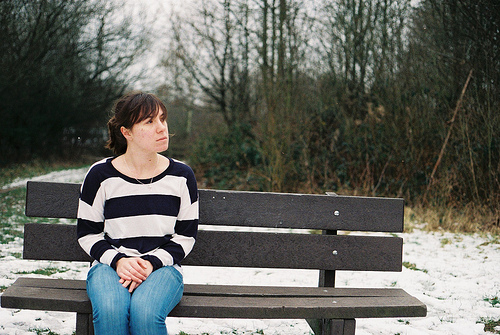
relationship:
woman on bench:
[114, 82, 165, 311] [256, 287, 296, 309]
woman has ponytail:
[114, 82, 165, 311] [106, 136, 128, 147]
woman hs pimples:
[114, 82, 165, 311] [141, 138, 151, 141]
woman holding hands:
[114, 82, 165, 311] [113, 260, 144, 286]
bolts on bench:
[328, 211, 341, 223] [256, 287, 296, 309]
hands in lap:
[113, 260, 144, 286] [114, 293, 137, 303]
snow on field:
[443, 284, 450, 287] [1, 216, 500, 335]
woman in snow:
[114, 82, 165, 311] [443, 284, 450, 287]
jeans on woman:
[109, 296, 172, 308] [114, 82, 165, 311]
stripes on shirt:
[129, 207, 164, 233] [167, 170, 182, 182]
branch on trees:
[266, 3, 301, 40] [256, 30, 316, 69]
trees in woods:
[256, 30, 316, 69] [44, 15, 158, 78]